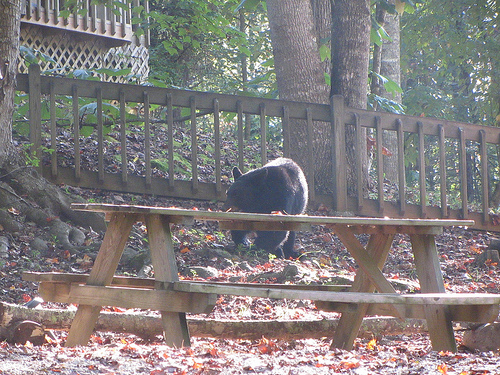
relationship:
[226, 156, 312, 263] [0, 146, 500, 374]
bear in park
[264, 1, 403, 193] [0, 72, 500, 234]
tree trunk behind fence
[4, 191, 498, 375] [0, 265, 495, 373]
leaves on ground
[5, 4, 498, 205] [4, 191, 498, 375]
trees have leaves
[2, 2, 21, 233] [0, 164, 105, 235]
tree has roots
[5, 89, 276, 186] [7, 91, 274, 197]
plants on hill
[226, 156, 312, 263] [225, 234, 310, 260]
bear on four feet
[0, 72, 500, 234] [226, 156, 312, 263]
fence behind bear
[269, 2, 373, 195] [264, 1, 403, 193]
tree has a tree trunk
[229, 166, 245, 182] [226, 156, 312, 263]
ear of bear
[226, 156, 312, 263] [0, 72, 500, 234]
bear beneath fence